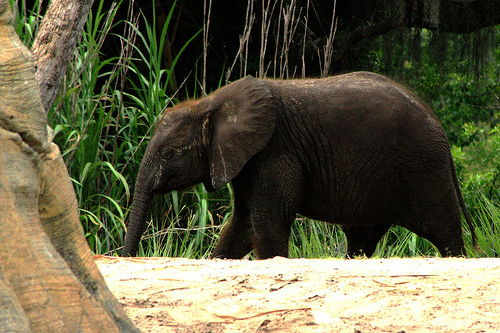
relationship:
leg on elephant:
[249, 202, 289, 258] [123, 72, 479, 258]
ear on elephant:
[207, 74, 275, 191] [123, 72, 479, 258]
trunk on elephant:
[122, 153, 153, 260] [123, 72, 479, 258]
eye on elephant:
[160, 150, 177, 158] [123, 72, 479, 258]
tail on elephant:
[447, 136, 480, 254] [123, 72, 479, 258]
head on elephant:
[143, 98, 214, 192] [123, 72, 479, 258]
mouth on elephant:
[157, 173, 172, 195] [123, 72, 479, 258]